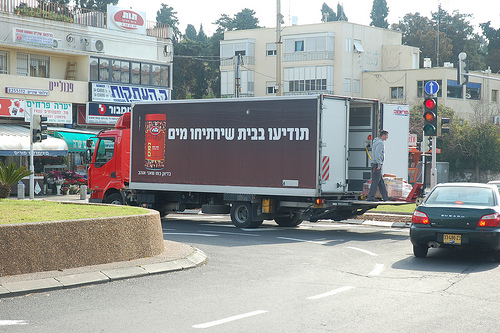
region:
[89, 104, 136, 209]
red truck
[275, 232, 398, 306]
white lines painted on cement road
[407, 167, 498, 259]
car parked on cement road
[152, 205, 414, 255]
shadow on the cement road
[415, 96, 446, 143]
black traffic light on post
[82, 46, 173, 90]
black windows of a building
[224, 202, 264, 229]
black tires of a truck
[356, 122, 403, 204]
man standing behind a truck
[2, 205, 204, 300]
thin grey sidewalk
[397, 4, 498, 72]
trees behind tall buildings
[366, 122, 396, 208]
This is a man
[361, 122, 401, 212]
This is a person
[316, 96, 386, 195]
This is a door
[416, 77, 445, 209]
These are traffic lights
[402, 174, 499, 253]
This is a car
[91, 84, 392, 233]
This is a truck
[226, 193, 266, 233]
Wheels of a truck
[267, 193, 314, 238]
Wheels of a truck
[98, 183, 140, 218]
Wheels of a truck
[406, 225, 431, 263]
Wheels of a car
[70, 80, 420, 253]
A delivery truck is on the road.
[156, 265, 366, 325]
White lines are painted on the street.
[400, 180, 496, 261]
The car is dark green.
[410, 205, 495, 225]
The car has two headlights.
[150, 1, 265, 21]
Trees are in the distance.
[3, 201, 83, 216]
The grass is green.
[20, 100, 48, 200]
The traffic lights are connected to a pole.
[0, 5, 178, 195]
A building in the background.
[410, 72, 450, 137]
An arrow sign on top of the traffic signal lights.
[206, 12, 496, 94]
The building is biege colored.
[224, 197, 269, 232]
These are wheels of a truck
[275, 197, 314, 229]
These are wheels of a truck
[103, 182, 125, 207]
These are wheels of a truck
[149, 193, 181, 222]
Wheels of a truck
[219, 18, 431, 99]
This is a building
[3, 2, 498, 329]
A city street scene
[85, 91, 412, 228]
A truck is parked on the street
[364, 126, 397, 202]
A man is standing on the truck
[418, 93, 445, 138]
A traffic light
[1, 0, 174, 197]
A building is in front of the truck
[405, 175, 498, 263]
A car is behind the truck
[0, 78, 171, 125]
Signs are on the building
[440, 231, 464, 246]
A license plate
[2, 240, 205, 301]
This is a sidewalk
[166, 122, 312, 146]
Writing is on the side of the truck